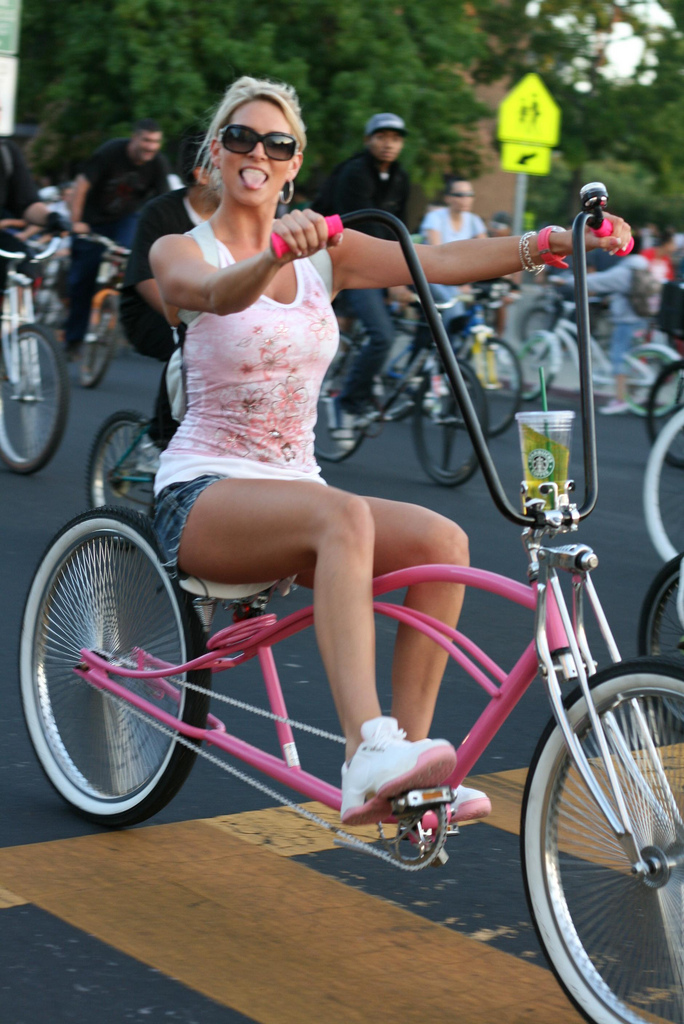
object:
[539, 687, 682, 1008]
spokes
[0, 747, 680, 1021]
line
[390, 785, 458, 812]
pedal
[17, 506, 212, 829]
tire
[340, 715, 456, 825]
shoes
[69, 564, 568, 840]
frame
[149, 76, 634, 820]
woman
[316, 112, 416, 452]
boy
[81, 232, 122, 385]
orangebike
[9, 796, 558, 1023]
stripes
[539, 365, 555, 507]
greenstraw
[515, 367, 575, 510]
cup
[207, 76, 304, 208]
head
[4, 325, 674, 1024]
street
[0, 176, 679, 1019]
bike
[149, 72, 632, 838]
girl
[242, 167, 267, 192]
tongue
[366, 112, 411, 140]
hat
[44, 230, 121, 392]
bike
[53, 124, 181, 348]
man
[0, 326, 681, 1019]
road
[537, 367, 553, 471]
straw